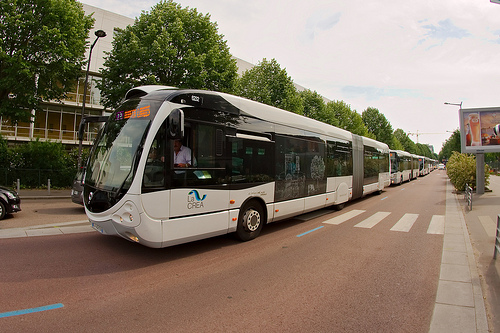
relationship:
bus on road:
[77, 80, 393, 253] [0, 166, 497, 332]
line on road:
[2, 296, 83, 316] [0, 166, 497, 332]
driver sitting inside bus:
[160, 130, 197, 174] [77, 80, 393, 253]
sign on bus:
[118, 100, 151, 120] [77, 80, 393, 253]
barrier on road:
[449, 176, 479, 200] [445, 146, 498, 265]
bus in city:
[77, 80, 393, 253] [12, 75, 496, 325]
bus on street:
[77, 80, 393, 253] [3, 165, 498, 315]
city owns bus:
[12, 151, 498, 325] [416, 153, 433, 178]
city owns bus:
[12, 151, 498, 325] [389, 149, 419, 186]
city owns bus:
[12, 151, 498, 325] [77, 80, 393, 253]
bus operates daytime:
[77, 80, 393, 253] [6, 5, 498, 331]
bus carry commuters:
[410, 154, 434, 179] [193, 133, 349, 168]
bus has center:
[77, 80, 393, 253] [346, 130, 367, 197]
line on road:
[398, 184, 406, 192] [0, 161, 448, 331]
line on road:
[377, 192, 389, 201] [0, 161, 448, 331]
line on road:
[294, 219, 326, 239] [0, 161, 448, 331]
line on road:
[2, 296, 83, 316] [0, 161, 448, 331]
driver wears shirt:
[160, 130, 197, 174] [168, 145, 198, 171]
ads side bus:
[272, 132, 329, 203] [77, 80, 393, 253]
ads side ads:
[328, 141, 353, 175] [402, 160, 410, 170]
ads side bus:
[364, 145, 381, 187] [77, 80, 393, 253]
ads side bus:
[379, 153, 390, 173] [77, 80, 393, 253]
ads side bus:
[402, 160, 410, 170] [77, 80, 393, 253]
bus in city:
[418, 152, 438, 174] [9, 35, 494, 329]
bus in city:
[389, 149, 419, 186] [9, 35, 494, 329]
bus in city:
[77, 80, 393, 253] [9, 35, 494, 329]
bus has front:
[77, 80, 393, 253] [85, 81, 158, 238]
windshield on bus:
[82, 96, 164, 212] [77, 80, 393, 253]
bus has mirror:
[77, 80, 393, 253] [168, 111, 185, 131]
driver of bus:
[160, 130, 197, 174] [77, 80, 393, 253]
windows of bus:
[188, 129, 277, 184] [77, 80, 393, 253]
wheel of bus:
[239, 205, 265, 240] [77, 80, 393, 253]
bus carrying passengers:
[77, 80, 393, 253] [235, 118, 430, 178]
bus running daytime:
[77, 80, 393, 253] [231, 8, 449, 89]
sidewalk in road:
[420, 194, 473, 326] [371, 196, 446, 322]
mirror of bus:
[167, 142, 220, 183] [67, 70, 442, 277]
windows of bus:
[281, 139, 352, 178] [77, 80, 393, 253]